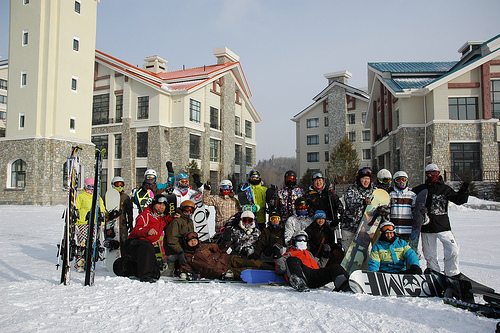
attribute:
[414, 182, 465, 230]
jacket — black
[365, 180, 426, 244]
shirt — striped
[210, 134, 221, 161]
window — rectangular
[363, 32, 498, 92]
roof — blue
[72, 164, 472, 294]
group — one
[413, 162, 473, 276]
person — one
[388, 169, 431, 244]
person — one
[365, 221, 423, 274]
person — one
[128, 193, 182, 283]
person — one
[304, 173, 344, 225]
person — one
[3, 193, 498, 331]
snow — some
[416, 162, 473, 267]
people — many, several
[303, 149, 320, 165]
window — rectangular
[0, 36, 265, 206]
building — one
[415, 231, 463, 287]
pants — white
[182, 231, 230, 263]
man — one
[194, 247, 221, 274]
coat — brown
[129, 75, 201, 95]
roof — red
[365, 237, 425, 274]
jacket — orange, gray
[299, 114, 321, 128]
window — rectangular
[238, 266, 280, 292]
snowboard — blue 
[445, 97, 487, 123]
window — rectangular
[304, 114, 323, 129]
window — rectangular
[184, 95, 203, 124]
window — rectangular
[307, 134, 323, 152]
window — rectangular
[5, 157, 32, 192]
window — rectangular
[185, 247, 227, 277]
jacket — brown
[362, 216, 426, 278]
person — green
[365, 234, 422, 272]
coat — blue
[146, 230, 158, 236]
hand — male, human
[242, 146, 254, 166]
window — rectangular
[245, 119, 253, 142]
window — rectangular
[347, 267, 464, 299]
snowboard — white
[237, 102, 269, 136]
window — rectangular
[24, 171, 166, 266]
person — one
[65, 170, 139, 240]
jacket — yellow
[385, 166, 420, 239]
man — one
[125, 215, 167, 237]
snow suit — red, one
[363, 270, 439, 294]
writing — black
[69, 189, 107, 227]
coat — yellow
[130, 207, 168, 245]
coat — red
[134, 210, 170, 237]
jacket — red